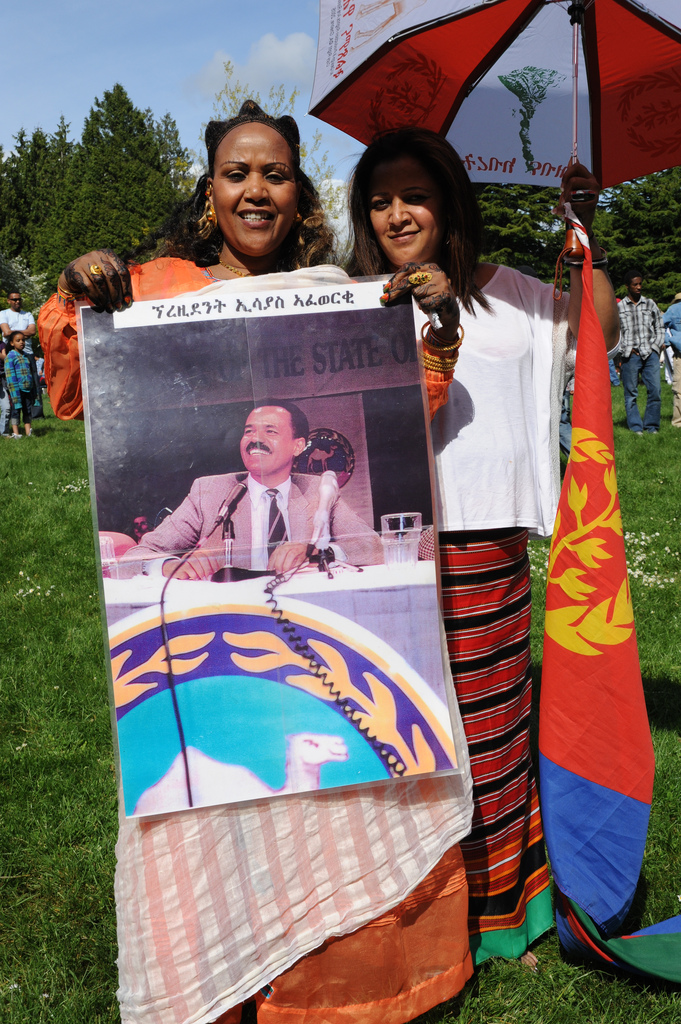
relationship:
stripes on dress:
[446, 524, 589, 907] [375, 220, 561, 1013]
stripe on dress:
[419, 487, 598, 912] [410, 267, 580, 926]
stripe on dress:
[435, 562, 532, 871] [415, 261, 584, 892]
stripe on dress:
[446, 565, 564, 832] [404, 267, 550, 1021]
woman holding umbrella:
[345, 118, 640, 984] [301, 8, 645, 209]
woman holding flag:
[345, 118, 640, 984] [504, 276, 641, 948]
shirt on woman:
[414, 253, 615, 584] [345, 118, 640, 984]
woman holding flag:
[345, 118, 640, 984] [541, 287, 626, 927]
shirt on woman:
[413, 265, 571, 536] [345, 118, 640, 984]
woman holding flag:
[345, 118, 640, 984] [562, 278, 627, 920]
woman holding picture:
[117, 95, 299, 971] [76, 277, 463, 818]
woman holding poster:
[41, 95, 469, 1023] [103, 277, 366, 766]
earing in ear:
[195, 211, 209, 239] [192, 183, 214, 229]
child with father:
[4, 328, 43, 438] [0, 260, 58, 413]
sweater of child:
[15, 341, 39, 410] [10, 323, 53, 454]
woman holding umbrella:
[345, 118, 640, 984] [316, 3, 606, 201]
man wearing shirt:
[613, 273, 664, 438] [618, 298, 665, 351]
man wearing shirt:
[613, 273, 664, 438] [614, 292, 668, 391]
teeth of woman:
[241, 206, 269, 223] [54, 95, 447, 419]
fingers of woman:
[374, 279, 395, 302] [31, 97, 453, 432]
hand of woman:
[52, 247, 138, 303] [31, 97, 453, 432]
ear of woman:
[192, 182, 214, 227] [44, 99, 452, 505]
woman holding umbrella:
[345, 118, 640, 984] [536, 179, 644, 1004]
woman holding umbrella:
[345, 118, 640, 985] [291, 3, 658, 220]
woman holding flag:
[345, 118, 640, 985] [517, 205, 659, 1020]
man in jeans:
[613, 278, 657, 427] [622, 347, 659, 422]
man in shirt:
[613, 278, 657, 427] [618, 297, 658, 356]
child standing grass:
[4, 328, 43, 438] [10, 440, 84, 1021]